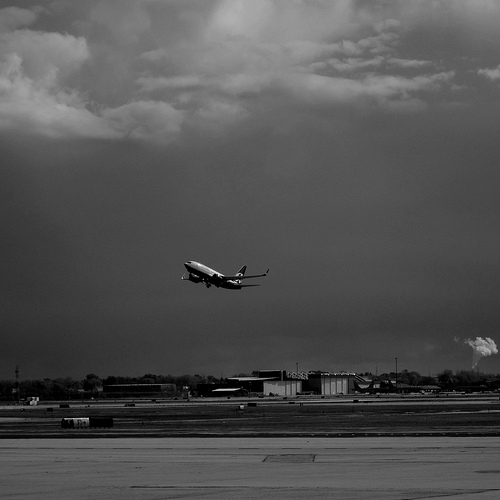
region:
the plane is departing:
[166, 236, 268, 315]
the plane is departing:
[165, 239, 281, 324]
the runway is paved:
[76, 431, 361, 494]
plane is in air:
[181, 263, 278, 298]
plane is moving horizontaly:
[170, 232, 288, 311]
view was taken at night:
[68, 261, 478, 442]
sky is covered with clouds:
[223, 52, 384, 111]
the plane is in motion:
[166, 225, 297, 326]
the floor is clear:
[195, 438, 265, 490]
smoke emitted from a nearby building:
[458, 329, 496, 372]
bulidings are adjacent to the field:
[231, 363, 371, 403]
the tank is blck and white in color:
[44, 408, 120, 433]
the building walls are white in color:
[271, 371, 349, 396]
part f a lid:
[271, 439, 307, 489]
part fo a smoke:
[469, 337, 489, 361]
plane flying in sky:
[170, 243, 277, 303]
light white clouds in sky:
[102, 56, 245, 156]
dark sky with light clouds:
[342, 135, 397, 186]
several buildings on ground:
[205, 359, 439, 400]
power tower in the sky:
[8, 357, 32, 379]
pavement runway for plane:
[132, 438, 321, 491]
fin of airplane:
[239, 261, 278, 286]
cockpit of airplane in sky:
[173, 253, 195, 274]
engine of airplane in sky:
[205, 269, 224, 284]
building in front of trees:
[85, 374, 190, 409]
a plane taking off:
[166, 240, 279, 311]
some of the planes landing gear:
[198, 278, 222, 293]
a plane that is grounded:
[355, 372, 447, 399]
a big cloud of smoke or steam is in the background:
[454, 334, 494, 380]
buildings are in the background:
[103, 350, 390, 410]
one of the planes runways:
[30, 433, 498, 490]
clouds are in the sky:
[10, 6, 418, 133]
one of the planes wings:
[224, 270, 276, 285]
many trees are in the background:
[9, 365, 494, 389]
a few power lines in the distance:
[288, 351, 408, 369]